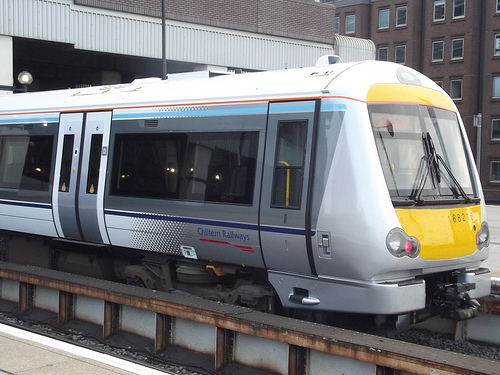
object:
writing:
[197, 225, 251, 241]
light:
[474, 219, 492, 251]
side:
[0, 97, 351, 282]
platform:
[1, 319, 176, 374]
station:
[0, 317, 174, 375]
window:
[273, 117, 312, 171]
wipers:
[423, 131, 471, 200]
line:
[0, 317, 173, 375]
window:
[429, 37, 448, 66]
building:
[330, 0, 500, 209]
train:
[0, 53, 495, 334]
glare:
[186, 167, 195, 172]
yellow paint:
[365, 82, 458, 114]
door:
[74, 110, 115, 248]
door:
[51, 110, 89, 245]